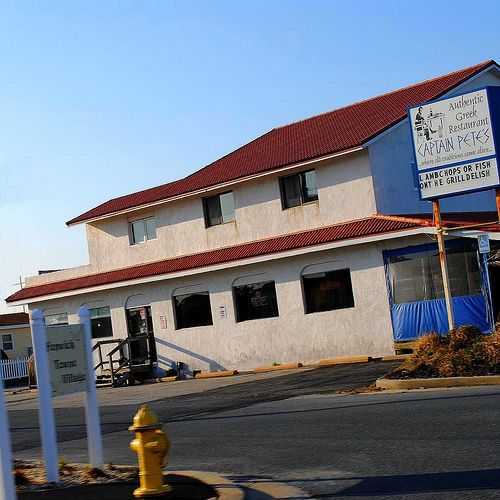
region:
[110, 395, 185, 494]
yellow fire hydrant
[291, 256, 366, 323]
window on side of building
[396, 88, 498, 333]
business sign outside of building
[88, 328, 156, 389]
staircase on front of house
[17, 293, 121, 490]
sign on wooden support poles on sidewalk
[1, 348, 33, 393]
white picket fence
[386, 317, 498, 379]
grass and hay pile on curb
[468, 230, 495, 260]
handicapped sign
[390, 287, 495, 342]
blue tarp attached to building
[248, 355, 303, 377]
yellow parking lot marker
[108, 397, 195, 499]
a yellow fire hydrant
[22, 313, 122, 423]
a white sign with black letters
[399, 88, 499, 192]
a white sign with black and blue letters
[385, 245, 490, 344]
a blue tarp and screen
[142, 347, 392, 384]
yellow stopping blocks for parking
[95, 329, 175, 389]
steps leading to the door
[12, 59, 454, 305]
a red roof on building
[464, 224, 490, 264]
a blue and white handicap sign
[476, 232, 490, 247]
a wheelchair on a sign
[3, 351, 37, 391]
a white picket fence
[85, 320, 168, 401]
a wooden staircase on a building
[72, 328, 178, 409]
a wooden staircase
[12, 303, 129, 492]
a white sign outside a building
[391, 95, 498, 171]
greek restaurant sign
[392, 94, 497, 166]
captain petes sign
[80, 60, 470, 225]
a building with a red roof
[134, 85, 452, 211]
a red roof on a building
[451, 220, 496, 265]
a handicap sign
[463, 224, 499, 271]
a handicap sign on a building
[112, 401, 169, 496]
yellow hydrant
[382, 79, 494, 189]
sign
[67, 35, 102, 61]
white clouds in blue sky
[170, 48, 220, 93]
white clouds in blue sky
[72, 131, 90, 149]
white clouds in blue sky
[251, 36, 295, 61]
white clouds in blue sky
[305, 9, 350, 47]
white clouds in blue sky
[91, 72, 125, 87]
white clouds in blue sky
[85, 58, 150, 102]
white clouds in blue sky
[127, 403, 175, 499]
yellow fire hydrant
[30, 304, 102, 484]
white sign and posts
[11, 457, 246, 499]
concrete curb beside road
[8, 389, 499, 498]
black asphalt road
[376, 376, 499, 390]
yellow concrete curb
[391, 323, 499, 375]
plants growing on concrete curb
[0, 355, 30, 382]
white picket fence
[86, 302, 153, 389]
entrance into Captain Pete's restaurant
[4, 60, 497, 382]
concrete restaurant with clay tile roof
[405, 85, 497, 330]
restaurant sign beside road